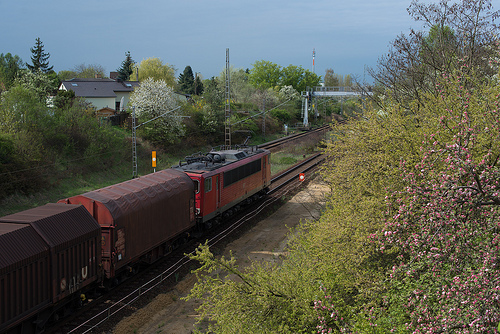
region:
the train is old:
[23, 75, 304, 325]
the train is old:
[52, 106, 277, 251]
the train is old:
[97, 137, 237, 284]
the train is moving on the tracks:
[8, 147, 294, 327]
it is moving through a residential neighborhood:
[24, 56, 400, 271]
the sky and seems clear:
[6, 1, 452, 121]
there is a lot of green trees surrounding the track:
[30, 102, 485, 274]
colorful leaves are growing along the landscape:
[346, 125, 496, 305]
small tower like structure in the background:
[300, 36, 320, 78]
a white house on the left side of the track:
[50, 70, 151, 110]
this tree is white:
[121, 75, 186, 140]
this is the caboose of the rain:
[10, 141, 290, 291]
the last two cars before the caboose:
[2, 166, 207, 321]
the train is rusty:
[92, 118, 208, 244]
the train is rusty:
[56, 78, 280, 223]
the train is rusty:
[49, 115, 214, 315]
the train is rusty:
[92, 130, 306, 327]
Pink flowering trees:
[386, 157, 486, 297]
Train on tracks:
[174, 152, 319, 209]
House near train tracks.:
[61, 49, 235, 141]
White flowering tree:
[107, 58, 192, 153]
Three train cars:
[2, 158, 272, 302]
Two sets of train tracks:
[270, 130, 331, 180]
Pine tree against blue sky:
[10, 18, 68, 92]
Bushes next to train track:
[205, 239, 343, 297]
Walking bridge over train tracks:
[298, 71, 418, 116]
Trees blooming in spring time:
[111, 25, 331, 127]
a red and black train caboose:
[187, 147, 273, 221]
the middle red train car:
[58, 165, 195, 275]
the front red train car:
[0, 191, 100, 332]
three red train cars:
[0, 143, 268, 333]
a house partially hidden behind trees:
[58, 80, 138, 112]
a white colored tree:
[130, 77, 178, 124]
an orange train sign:
[150, 148, 156, 166]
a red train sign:
[299, 171, 304, 181]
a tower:
[312, 48, 315, 90]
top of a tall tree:
[27, 38, 50, 71]